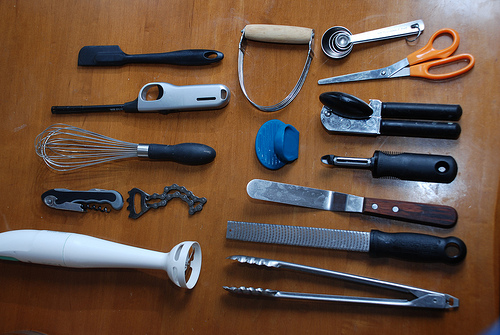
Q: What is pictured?
A: Kitchen utensils.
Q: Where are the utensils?
A: On a table.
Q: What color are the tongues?
A: Silver.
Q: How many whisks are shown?
A: One.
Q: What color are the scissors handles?
A: Orange.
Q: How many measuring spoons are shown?
A: Five.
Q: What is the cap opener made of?
A: A bicycle chain.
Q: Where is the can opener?
A: Next to the scissors.